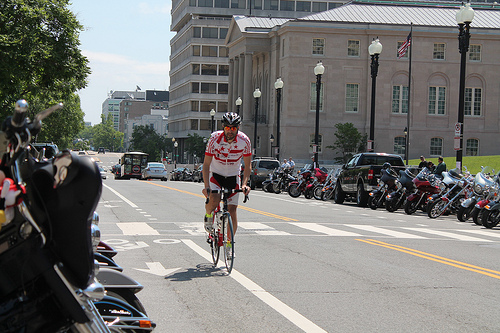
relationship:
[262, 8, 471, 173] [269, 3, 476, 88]
street lights has globes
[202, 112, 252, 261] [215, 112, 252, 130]
rider has helmet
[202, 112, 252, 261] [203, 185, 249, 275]
rider riding bike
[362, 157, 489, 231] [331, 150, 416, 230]
motorcycle parked around truck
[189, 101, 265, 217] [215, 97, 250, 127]
rider wearing helmet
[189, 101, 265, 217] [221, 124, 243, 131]
rider wearing sunglasses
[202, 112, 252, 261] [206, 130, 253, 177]
rider wearing shirt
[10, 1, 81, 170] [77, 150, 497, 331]
trees hanging over street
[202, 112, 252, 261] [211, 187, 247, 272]
rider riding bike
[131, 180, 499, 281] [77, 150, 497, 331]
line in street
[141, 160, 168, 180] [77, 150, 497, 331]
car on street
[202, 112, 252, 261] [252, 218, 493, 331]
rider on street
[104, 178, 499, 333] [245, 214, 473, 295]
line on street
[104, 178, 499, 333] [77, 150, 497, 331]
line in street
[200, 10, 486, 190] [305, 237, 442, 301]
lights along street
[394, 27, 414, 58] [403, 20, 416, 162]
flag on pole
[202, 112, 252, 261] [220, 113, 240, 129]
rider wearing helmet